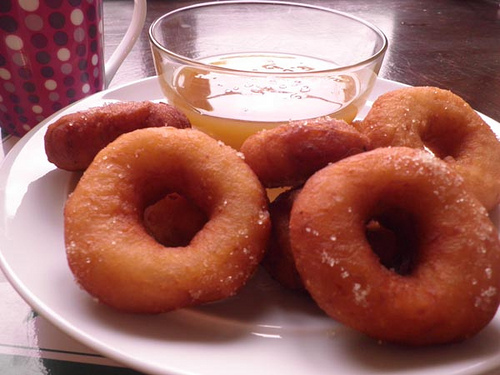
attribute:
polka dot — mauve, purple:
[28, 31, 49, 50]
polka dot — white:
[57, 48, 71, 62]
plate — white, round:
[0, 74, 500, 375]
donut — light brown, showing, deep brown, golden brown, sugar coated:
[63, 125, 273, 316]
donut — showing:
[288, 145, 500, 345]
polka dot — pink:
[11, 52, 29, 68]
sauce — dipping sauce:
[174, 51, 361, 153]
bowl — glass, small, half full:
[147, 0, 389, 153]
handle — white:
[104, 0, 148, 90]